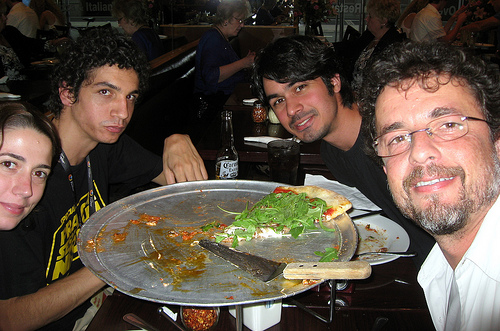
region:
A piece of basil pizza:
[189, 161, 363, 259]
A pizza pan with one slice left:
[63, 140, 378, 317]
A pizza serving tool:
[188, 217, 375, 310]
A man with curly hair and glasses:
[344, 27, 498, 261]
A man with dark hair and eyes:
[238, 32, 353, 153]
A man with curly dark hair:
[46, 12, 164, 154]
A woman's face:
[1, 91, 61, 261]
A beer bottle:
[190, 97, 258, 189]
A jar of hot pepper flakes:
[169, 297, 234, 329]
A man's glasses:
[369, 106, 481, 161]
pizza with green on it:
[181, 180, 368, 270]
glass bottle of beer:
[195, 93, 266, 204]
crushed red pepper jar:
[161, 299, 223, 327]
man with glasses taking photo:
[356, 49, 489, 257]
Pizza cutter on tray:
[201, 229, 383, 288]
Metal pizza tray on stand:
[60, 175, 437, 305]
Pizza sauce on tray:
[130, 204, 226, 298]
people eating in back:
[141, 3, 333, 176]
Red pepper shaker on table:
[245, 91, 279, 121]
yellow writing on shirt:
[44, 212, 121, 305]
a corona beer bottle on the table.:
[204, 106, 248, 181]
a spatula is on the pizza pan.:
[191, 234, 375, 297]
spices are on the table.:
[243, 103, 278, 129]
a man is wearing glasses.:
[348, 35, 498, 235]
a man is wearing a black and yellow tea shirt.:
[36, 30, 141, 283]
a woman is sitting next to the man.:
[1, 95, 69, 247]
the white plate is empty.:
[340, 207, 409, 272]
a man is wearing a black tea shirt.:
[256, 42, 383, 202]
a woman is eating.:
[189, 0, 273, 98]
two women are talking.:
[190, 0, 415, 42]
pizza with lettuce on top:
[227, 177, 348, 262]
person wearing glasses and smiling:
[334, 92, 494, 197]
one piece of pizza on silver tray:
[124, 183, 334, 299]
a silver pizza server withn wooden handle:
[160, 233, 371, 309]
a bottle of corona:
[207, 98, 247, 182]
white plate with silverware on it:
[352, 217, 408, 295]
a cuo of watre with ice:
[255, 138, 302, 183]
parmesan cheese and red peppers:
[246, 100, 282, 128]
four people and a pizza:
[14, 42, 470, 239]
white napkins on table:
[277, 168, 374, 237]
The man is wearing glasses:
[354, 113, 495, 158]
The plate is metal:
[77, 172, 356, 302]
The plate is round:
[77, 180, 361, 295]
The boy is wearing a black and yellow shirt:
[31, 53, 191, 264]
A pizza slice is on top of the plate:
[186, 197, 366, 244]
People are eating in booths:
[13, 5, 468, 93]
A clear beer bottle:
[207, 103, 262, 200]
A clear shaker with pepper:
[148, 273, 228, 324]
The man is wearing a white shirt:
[354, 68, 496, 315]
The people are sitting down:
[18, 30, 481, 305]